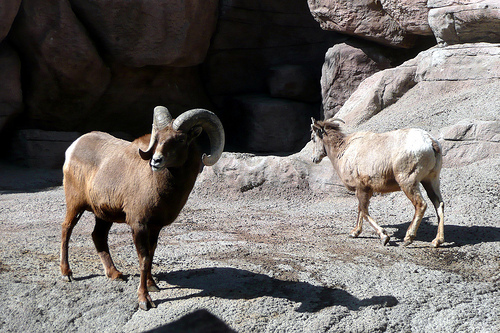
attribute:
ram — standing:
[303, 110, 458, 253]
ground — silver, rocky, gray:
[0, 166, 498, 332]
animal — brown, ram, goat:
[310, 117, 450, 251]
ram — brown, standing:
[59, 106, 227, 310]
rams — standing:
[61, 104, 448, 310]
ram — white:
[310, 117, 447, 248]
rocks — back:
[267, 7, 498, 167]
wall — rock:
[1, 1, 498, 157]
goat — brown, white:
[307, 115, 453, 248]